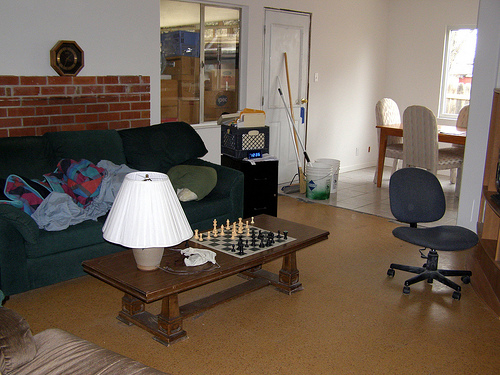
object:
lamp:
[101, 169, 195, 272]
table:
[80, 214, 331, 347]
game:
[190, 217, 298, 260]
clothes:
[0, 158, 140, 231]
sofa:
[0, 121, 245, 298]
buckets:
[306, 159, 341, 200]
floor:
[279, 164, 457, 233]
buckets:
[305, 162, 332, 200]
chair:
[385, 167, 480, 300]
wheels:
[460, 275, 470, 284]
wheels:
[451, 291, 461, 301]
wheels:
[402, 286, 410, 295]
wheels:
[386, 268, 395, 277]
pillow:
[166, 165, 217, 202]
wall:
[0, 0, 162, 138]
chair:
[449, 105, 472, 184]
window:
[438, 28, 478, 119]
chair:
[372, 97, 417, 184]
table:
[374, 120, 467, 188]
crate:
[220, 123, 270, 158]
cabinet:
[220, 153, 279, 221]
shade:
[99, 170, 193, 249]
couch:
[1, 307, 179, 375]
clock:
[48, 39, 86, 78]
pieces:
[283, 231, 289, 240]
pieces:
[238, 243, 244, 255]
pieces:
[259, 237, 265, 249]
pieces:
[250, 217, 255, 224]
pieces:
[212, 219, 218, 234]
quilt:
[1, 158, 107, 215]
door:
[260, 7, 312, 186]